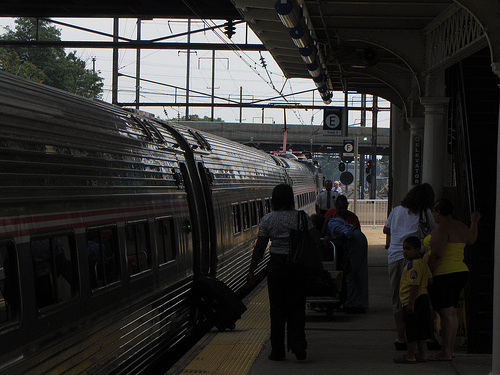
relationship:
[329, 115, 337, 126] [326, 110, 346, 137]
e on sign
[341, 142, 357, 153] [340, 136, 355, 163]
letter on sign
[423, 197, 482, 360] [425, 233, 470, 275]
lady wearing shirt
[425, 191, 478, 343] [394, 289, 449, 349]
lady wearing shorts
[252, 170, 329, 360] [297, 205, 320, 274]
lady carrying purse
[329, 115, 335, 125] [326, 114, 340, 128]
e in circle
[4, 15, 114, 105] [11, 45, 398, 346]
trees behind train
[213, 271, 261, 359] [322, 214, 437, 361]
line on pavement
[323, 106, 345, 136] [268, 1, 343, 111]
sign attached pole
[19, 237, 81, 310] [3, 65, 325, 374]
window on side of train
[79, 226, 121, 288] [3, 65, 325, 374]
window on side of train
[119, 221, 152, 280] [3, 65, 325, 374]
window on side of train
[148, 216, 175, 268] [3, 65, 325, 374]
window on side of train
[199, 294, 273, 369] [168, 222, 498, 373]
yellow line on platform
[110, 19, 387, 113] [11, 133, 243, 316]
scaffolding above train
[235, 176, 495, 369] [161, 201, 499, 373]
people at platform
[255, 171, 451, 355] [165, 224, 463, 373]
people at pavement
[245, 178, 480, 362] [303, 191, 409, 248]
people on platform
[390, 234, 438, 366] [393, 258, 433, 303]
boy in yellow shirt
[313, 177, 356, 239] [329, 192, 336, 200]
man with badge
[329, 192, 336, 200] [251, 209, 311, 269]
badge on shirt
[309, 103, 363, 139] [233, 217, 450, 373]
sign hanging from overhead platform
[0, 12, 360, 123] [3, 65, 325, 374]
lines above train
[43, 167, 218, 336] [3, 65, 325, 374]
windows on train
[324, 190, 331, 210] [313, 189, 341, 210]
tie on shirt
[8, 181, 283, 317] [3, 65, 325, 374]
windows on train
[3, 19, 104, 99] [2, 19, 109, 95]
leaves on tree